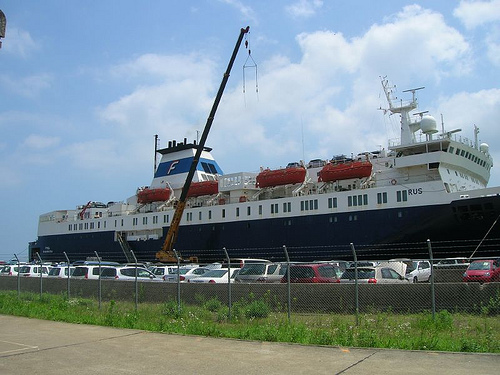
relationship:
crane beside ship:
[156, 17, 262, 263] [26, 140, 497, 253]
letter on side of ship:
[164, 159, 182, 172] [26, 140, 497, 253]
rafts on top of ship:
[139, 158, 375, 190] [26, 140, 497, 253]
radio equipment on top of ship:
[364, 76, 471, 151] [26, 140, 497, 253]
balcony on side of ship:
[64, 204, 499, 244] [26, 140, 497, 253]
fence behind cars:
[9, 241, 499, 314] [2, 254, 489, 288]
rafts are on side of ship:
[139, 158, 375, 190] [26, 140, 497, 253]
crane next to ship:
[156, 17, 262, 263] [26, 140, 497, 253]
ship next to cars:
[26, 140, 497, 253] [2, 254, 489, 288]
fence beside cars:
[9, 241, 499, 314] [2, 254, 489, 288]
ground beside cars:
[2, 313, 496, 374] [2, 254, 489, 288]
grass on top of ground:
[2, 283, 500, 346] [2, 313, 496, 374]